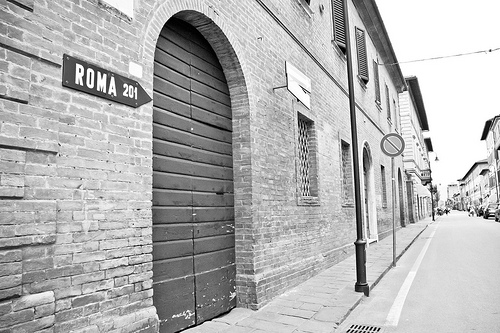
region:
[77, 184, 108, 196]
brick on side of building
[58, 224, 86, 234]
brick on side of building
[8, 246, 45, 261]
brick on side of building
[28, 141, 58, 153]
brick on side of building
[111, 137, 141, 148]
brick on side of building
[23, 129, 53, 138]
brick on side of building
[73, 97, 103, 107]
brick on side of building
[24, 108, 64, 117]
brick on side of building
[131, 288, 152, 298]
brick on side of building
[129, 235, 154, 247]
brick on side of building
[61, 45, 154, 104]
Black arrow shaped sign with white letters reading Roma 201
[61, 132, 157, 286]
Brick wall with chipped and damaged bricks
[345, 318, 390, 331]
Sewer grate with many wholes in the asphalt road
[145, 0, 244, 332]
Thick door under a brick archway with chipped paint on the bottom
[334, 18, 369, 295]
Tall thin gray pole of a street lamp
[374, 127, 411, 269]
Round sign on a pole with a circle design and a crossing line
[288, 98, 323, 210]
Window in the side of a brick building with metal grating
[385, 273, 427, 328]
Light colored line on the side of an asphalt road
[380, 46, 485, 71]
Thin dark colored cable crossing the street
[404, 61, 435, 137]
Roof of a brick building protruding forward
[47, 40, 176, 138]
Arrow on a building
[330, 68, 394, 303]
Pole on the street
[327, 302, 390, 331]
sewer gate on the street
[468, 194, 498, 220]
cars parked on street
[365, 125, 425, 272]
no parking street signs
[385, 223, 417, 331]
white line on the street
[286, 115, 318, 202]
gate on a window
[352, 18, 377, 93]
shutter on the window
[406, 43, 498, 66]
Electric wire going from building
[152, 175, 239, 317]
wooden door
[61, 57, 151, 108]
white lettering on black sign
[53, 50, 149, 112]
black sign with pointed end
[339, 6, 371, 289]
black street lamp pole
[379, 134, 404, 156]
round street sign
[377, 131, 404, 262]
street sign on pole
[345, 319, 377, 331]
grate in the street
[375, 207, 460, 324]
white line painted on the street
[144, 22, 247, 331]
entrance to the building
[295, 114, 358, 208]
two windows on side of building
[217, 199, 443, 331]
sidewalk in front of building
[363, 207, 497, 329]
road is paved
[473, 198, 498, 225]
cars parked along roadside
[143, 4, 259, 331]
rounded garage door on building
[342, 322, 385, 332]
sewer grate on road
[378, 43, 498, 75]
electric wire going across road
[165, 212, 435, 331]
brick sidewalk runs alongside road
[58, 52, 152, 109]
sign on brick building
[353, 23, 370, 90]
window has shutters on outside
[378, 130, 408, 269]
no parking sign on side of street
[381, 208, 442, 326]
white line painted on side of road